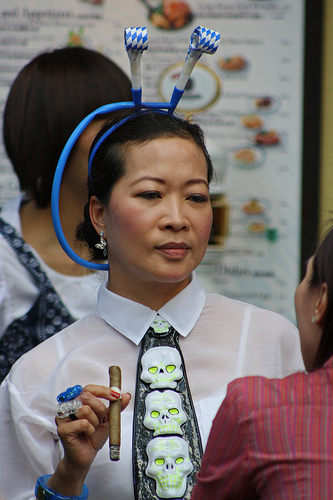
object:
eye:
[131, 189, 162, 199]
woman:
[0, 109, 305, 497]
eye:
[184, 192, 208, 201]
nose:
[157, 202, 189, 231]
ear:
[88, 195, 107, 240]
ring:
[55, 383, 83, 404]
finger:
[67, 402, 99, 428]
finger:
[61, 417, 95, 436]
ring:
[53, 399, 85, 419]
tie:
[133, 315, 203, 497]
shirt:
[0, 269, 306, 498]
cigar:
[109, 364, 121, 462]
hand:
[55, 385, 132, 471]